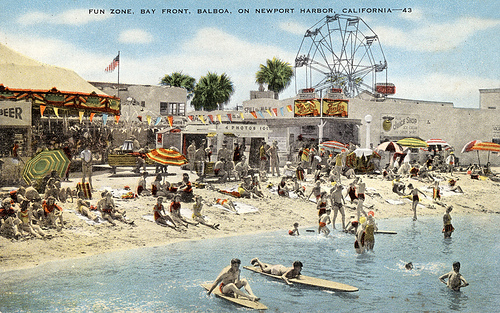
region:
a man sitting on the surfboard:
[206, 256, 267, 309]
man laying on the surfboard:
[251, 258, 358, 293]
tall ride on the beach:
[296, 16, 393, 94]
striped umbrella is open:
[146, 147, 186, 163]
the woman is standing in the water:
[441, 261, 468, 289]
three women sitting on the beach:
[149, 193, 222, 226]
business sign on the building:
[293, 100, 349, 115]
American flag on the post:
[103, 53, 119, 73]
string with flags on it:
[36, 103, 300, 128]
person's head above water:
[401, 263, 415, 270]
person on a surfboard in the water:
[191, 256, 270, 311]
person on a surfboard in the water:
[240, 248, 360, 308]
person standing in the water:
[435, 256, 472, 299]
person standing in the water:
[438, 203, 459, 238]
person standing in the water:
[350, 215, 372, 257]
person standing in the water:
[363, 209, 381, 255]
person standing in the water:
[315, 205, 335, 239]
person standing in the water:
[328, 184, 351, 232]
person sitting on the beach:
[148, 192, 182, 234]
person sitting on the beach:
[189, 195, 224, 232]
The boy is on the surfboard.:
[248, 252, 386, 312]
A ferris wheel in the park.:
[288, 3, 410, 107]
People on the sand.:
[128, 145, 433, 211]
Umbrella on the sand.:
[147, 128, 198, 168]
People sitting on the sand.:
[137, 190, 219, 222]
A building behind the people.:
[272, 91, 462, 151]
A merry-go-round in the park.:
[39, 101, 121, 148]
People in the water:
[406, 203, 467, 290]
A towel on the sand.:
[215, 190, 273, 217]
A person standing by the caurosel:
[70, 135, 110, 196]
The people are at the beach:
[5, 85, 497, 310]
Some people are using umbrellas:
[10, 125, 497, 305]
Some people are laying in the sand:
[11, 92, 491, 307]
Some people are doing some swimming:
[21, 108, 496, 308]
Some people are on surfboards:
[7, 82, 489, 309]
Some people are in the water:
[20, 90, 495, 306]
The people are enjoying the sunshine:
[0, 115, 495, 303]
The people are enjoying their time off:
[3, 118, 490, 299]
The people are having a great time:
[6, 112, 491, 300]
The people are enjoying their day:
[15, 120, 498, 302]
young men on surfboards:
[185, 249, 360, 312]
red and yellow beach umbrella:
[143, 142, 193, 172]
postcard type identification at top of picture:
[75, 1, 420, 22]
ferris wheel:
[284, 6, 412, 93]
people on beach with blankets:
[134, 187, 264, 235]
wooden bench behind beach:
[102, 144, 151, 214]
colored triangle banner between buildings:
[37, 98, 331, 136]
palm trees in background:
[157, 54, 292, 114]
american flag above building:
[96, 41, 133, 100]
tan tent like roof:
[2, 47, 116, 110]